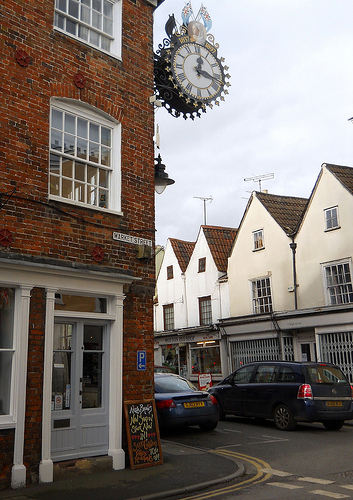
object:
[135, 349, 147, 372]
sign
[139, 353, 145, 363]
p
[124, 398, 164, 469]
menu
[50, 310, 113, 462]
door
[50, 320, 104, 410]
windows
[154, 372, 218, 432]
car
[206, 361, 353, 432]
van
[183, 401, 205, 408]
license plate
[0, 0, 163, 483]
shop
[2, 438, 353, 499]
sidewalk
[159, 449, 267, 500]
line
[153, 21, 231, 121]
clock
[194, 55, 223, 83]
hands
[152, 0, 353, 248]
sky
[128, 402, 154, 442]
writing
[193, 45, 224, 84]
12:15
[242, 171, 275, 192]
antenna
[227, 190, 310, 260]
roofs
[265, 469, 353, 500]
lines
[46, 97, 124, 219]
windows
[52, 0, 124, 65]
windows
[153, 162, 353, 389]
building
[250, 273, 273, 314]
windows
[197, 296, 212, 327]
windows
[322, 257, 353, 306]
windows